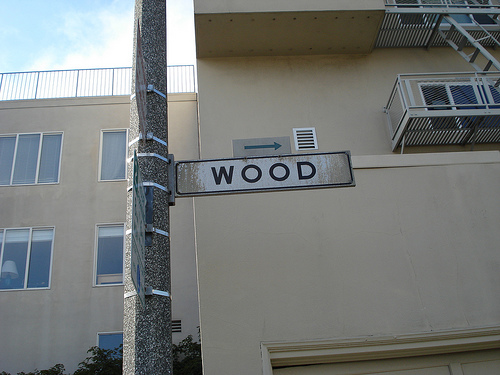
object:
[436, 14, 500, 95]
ladder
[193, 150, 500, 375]
wall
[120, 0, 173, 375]
mast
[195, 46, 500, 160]
wall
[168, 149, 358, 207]
sign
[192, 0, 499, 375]
building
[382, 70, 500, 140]
railing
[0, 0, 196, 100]
cloud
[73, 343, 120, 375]
plant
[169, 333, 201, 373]
plant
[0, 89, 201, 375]
wall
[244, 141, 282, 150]
arrow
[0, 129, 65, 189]
windows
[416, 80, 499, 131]
windows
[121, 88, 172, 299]
rungs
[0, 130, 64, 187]
glass window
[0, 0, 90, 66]
sky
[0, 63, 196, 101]
metal bars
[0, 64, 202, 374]
building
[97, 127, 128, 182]
window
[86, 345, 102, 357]
leaves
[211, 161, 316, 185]
letters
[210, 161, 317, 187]
english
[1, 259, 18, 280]
shade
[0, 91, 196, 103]
roof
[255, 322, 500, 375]
frame